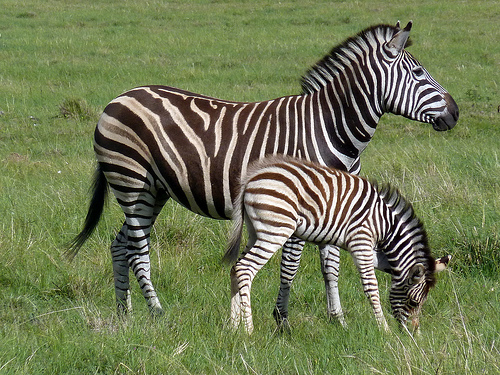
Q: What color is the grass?
A: Green.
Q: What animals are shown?
A: Zebras.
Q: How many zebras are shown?
A: Two.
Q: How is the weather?
A: Clear.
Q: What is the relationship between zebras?
A: One is older.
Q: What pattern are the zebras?
A: Striped.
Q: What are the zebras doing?
A: Grazing.